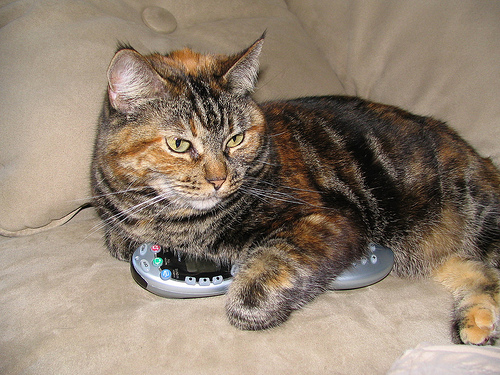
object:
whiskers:
[236, 182, 334, 215]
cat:
[71, 27, 498, 346]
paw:
[451, 295, 498, 345]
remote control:
[129, 226, 401, 298]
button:
[137, 5, 179, 37]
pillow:
[4, 3, 337, 211]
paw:
[227, 274, 287, 330]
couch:
[0, 2, 497, 372]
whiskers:
[64, 183, 167, 204]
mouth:
[167, 190, 239, 212]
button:
[140, 5, 178, 32]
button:
[151, 256, 164, 267]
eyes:
[221, 124, 250, 149]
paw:
[448, 288, 498, 348]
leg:
[386, 221, 498, 351]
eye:
[163, 133, 193, 154]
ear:
[102, 37, 168, 113]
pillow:
[2, 3, 305, 31]